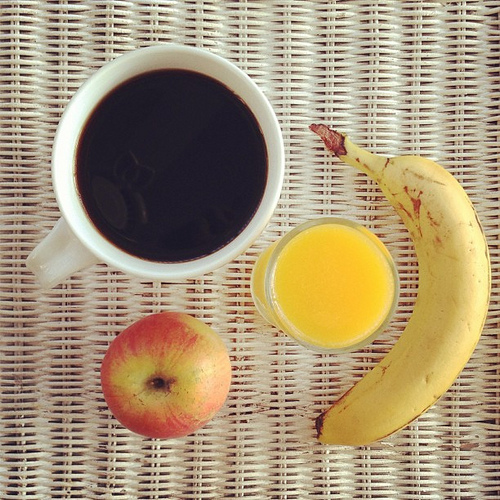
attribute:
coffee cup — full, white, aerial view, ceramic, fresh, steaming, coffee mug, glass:
[27, 42, 288, 304]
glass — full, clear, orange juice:
[249, 215, 406, 355]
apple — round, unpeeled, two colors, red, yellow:
[98, 310, 237, 440]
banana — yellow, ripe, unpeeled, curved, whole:
[307, 119, 496, 451]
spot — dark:
[312, 410, 328, 437]